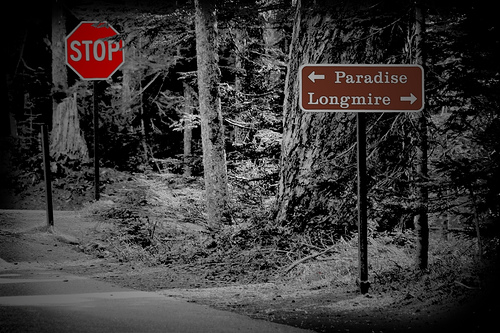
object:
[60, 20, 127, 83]
stop sign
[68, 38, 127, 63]
letters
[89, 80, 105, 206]
pole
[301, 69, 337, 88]
arrow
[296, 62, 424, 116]
sign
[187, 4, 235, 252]
trees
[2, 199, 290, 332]
street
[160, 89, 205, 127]
branch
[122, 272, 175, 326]
dirt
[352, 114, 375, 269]
post